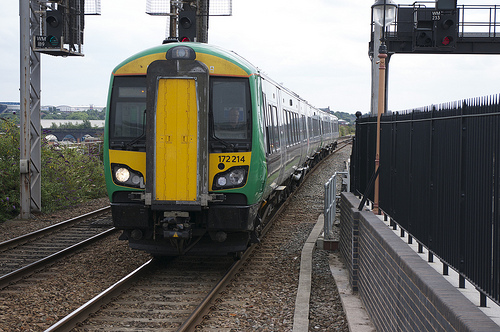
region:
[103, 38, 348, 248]
a short green and yellow train on the track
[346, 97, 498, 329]
a tall fence next to the train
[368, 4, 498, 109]
a pole with some lights next to the train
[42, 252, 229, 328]
the track the train is sitting on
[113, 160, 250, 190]
the lights on the front of the train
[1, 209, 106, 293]
the other track next to the train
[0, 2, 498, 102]
the sunny sky above the train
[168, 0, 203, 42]
some more lights above the train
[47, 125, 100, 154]
some buildings off to the side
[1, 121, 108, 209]
some bushes off to the side of the train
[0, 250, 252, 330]
Two train tracks on the ground.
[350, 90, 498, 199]
The black iron fence.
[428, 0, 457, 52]
The traffic light hanging above.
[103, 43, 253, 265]
The yellow and green train.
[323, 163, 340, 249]
The silver gate next to train.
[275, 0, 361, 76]
The pale white sky.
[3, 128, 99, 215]
The green patch of bushes.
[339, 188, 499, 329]
The low brick wall.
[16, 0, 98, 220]
A utility area pole.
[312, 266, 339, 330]
The multicolored gravel stones.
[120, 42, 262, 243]
front of a train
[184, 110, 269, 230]
train's number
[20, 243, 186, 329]
train tracks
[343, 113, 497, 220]
black fence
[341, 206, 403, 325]
brick wall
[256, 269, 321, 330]
gravel and rocks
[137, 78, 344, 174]
passenger train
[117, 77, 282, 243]
one headlight lit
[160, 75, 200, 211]
yellow door on a train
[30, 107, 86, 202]
lush greenery on a cloudy day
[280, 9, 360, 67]
part of a cloudy sky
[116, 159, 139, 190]
part of a headlight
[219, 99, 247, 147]
part of a window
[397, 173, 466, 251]
part of a fence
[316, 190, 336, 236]
part of some metal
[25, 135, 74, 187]
part of some green plants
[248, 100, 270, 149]
edge of the train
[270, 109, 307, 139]
part of some windows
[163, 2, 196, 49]
part of a traffic light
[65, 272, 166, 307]
shiny black train track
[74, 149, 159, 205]
light in front of train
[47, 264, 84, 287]
pebble in the middle of the track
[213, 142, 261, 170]
large black number on the track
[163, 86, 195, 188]
large yellow train door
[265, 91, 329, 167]
silver side of train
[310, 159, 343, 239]
large silver short railing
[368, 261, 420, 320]
pink lines in wall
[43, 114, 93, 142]
large roof on building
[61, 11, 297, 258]
large green and yellow train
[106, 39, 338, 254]
a green and yellow train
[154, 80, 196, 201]
a yellow door on the front of the train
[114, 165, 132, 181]
a headlight on the train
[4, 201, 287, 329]
the train tracks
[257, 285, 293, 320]
rocks next to the train tracks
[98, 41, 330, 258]
yellow green and silver train on tracks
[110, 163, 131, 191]
lit train headlight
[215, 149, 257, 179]
black numbers on yellow door